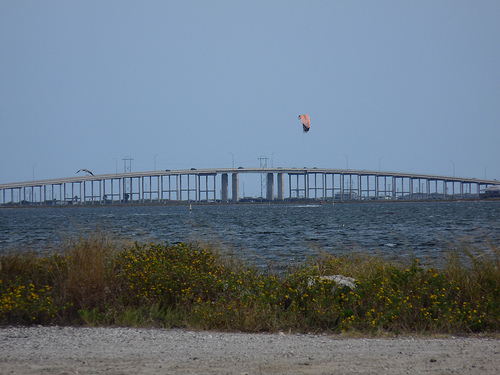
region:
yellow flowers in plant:
[375, 272, 472, 346]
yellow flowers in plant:
[294, 278, 355, 325]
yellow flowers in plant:
[192, 243, 246, 310]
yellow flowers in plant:
[141, 238, 179, 293]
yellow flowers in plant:
[118, 236, 145, 287]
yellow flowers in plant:
[4, 283, 39, 325]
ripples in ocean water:
[247, 219, 299, 261]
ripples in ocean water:
[171, 206, 233, 240]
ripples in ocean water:
[74, 198, 141, 239]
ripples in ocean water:
[21, 202, 59, 247]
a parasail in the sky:
[226, 58, 390, 185]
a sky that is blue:
[100, 12, 250, 84]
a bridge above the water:
[44, 104, 499, 298]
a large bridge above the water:
[129, 119, 496, 286]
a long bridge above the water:
[73, 122, 465, 277]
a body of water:
[250, 195, 497, 257]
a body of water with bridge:
[123, 151, 400, 283]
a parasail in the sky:
[283, 89, 349, 161]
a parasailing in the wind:
[276, 79, 355, 168]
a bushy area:
[139, 239, 446, 373]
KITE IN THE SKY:
[274, 92, 313, 136]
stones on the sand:
[170, 319, 260, 345]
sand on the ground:
[291, 345, 443, 364]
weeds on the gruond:
[200, 278, 382, 306]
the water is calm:
[220, 217, 270, 240]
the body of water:
[349, 208, 409, 243]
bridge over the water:
[30, 151, 202, 198]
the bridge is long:
[239, 160, 408, 202]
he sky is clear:
[59, 58, 157, 118]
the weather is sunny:
[326, 68, 426, 149]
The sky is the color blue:
[28, 10, 429, 96]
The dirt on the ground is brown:
[11, 331, 476, 372]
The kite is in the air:
[289, 105, 321, 142]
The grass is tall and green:
[77, 228, 457, 330]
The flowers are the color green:
[103, 242, 267, 317]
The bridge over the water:
[52, 153, 474, 209]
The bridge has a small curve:
[20, 160, 482, 205]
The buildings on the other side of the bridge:
[322, 182, 474, 212]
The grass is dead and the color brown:
[51, 215, 132, 320]